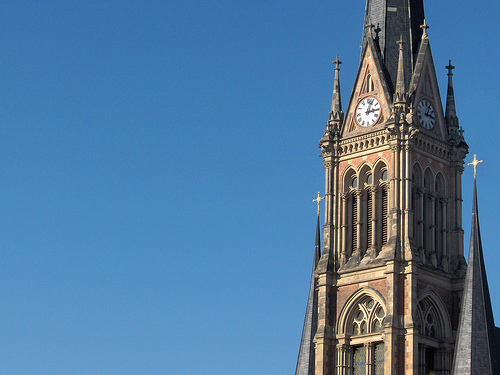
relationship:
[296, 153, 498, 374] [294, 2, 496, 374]
spires next to tower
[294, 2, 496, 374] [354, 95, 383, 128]
tower has clock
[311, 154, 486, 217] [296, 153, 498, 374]
crosses on top of spires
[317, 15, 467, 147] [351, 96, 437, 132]
spires next to clocks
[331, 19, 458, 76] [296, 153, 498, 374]
crosses on top of spires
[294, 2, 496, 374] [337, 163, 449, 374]
tower has windows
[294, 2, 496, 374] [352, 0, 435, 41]
tower has steeple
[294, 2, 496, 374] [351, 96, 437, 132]
tower has clocks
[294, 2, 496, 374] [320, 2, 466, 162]
tower has tops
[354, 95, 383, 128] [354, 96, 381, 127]
clock has numbers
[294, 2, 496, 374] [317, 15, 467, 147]
tower has spires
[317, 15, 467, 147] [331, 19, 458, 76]
spires has crosses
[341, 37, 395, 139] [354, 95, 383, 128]
panel around clock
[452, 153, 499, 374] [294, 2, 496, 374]
spire next to tower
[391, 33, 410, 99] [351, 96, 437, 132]
spire between clocks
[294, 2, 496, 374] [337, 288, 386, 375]
tower has window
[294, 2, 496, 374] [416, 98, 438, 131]
tower has clock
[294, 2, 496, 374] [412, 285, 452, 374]
tower has window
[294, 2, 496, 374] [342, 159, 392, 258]
tower has third window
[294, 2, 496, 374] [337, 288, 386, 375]
tower has first window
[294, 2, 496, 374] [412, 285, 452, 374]
tower has second window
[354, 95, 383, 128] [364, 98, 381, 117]
clock has hands